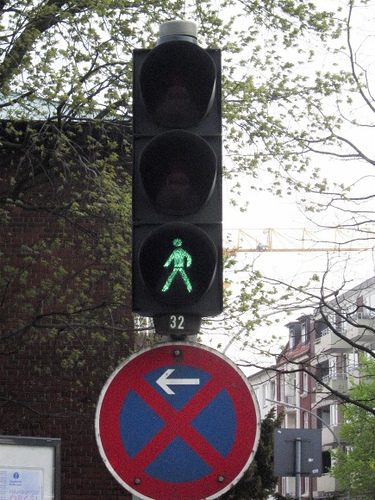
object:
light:
[160, 235, 196, 295]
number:
[168, 314, 185, 330]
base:
[129, 36, 226, 337]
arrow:
[154, 367, 200, 396]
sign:
[90, 338, 263, 499]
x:
[129, 373, 224, 472]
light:
[129, 33, 226, 336]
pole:
[293, 435, 302, 499]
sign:
[272, 426, 323, 479]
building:
[313, 273, 375, 500]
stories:
[310, 390, 347, 445]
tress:
[6, 182, 18, 211]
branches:
[319, 374, 325, 390]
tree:
[0, 0, 137, 354]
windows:
[301, 321, 310, 347]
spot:
[165, 372, 169, 375]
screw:
[173, 348, 182, 357]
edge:
[91, 367, 109, 479]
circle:
[97, 341, 260, 500]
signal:
[138, 217, 221, 311]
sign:
[0, 432, 66, 498]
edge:
[52, 439, 64, 500]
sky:
[0, 0, 375, 376]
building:
[0, 117, 137, 500]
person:
[160, 236, 194, 294]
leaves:
[243, 292, 249, 304]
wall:
[0, 119, 136, 499]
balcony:
[320, 331, 353, 354]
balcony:
[351, 317, 375, 342]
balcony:
[314, 381, 347, 410]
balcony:
[321, 421, 356, 446]